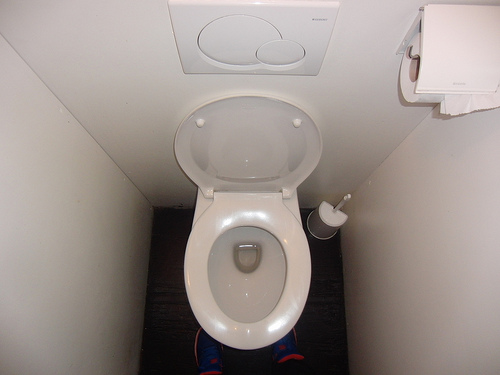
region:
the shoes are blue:
[173, 331, 311, 364]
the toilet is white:
[180, 216, 300, 311]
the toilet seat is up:
[175, 141, 322, 198]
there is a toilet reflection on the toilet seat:
[211, 140, 298, 184]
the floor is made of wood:
[153, 235, 178, 357]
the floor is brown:
[147, 253, 179, 346]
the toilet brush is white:
[307, 199, 349, 238]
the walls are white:
[408, 215, 488, 297]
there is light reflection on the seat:
[203, 210, 293, 332]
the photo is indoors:
[2, 127, 499, 372]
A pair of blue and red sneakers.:
[178, 322, 303, 372]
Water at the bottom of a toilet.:
[223, 239, 267, 279]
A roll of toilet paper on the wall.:
[390, 43, 494, 121]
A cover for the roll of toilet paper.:
[411, 7, 499, 106]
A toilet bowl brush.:
[303, 191, 355, 242]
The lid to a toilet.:
[160, 93, 334, 201]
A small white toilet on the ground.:
[166, 93, 325, 359]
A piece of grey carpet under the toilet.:
[137, 191, 356, 373]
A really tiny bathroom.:
[3, 1, 495, 371]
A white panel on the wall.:
[164, 2, 342, 87]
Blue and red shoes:
[180, 315, 311, 372]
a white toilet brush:
[310, 190, 351, 245]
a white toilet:
[156, 81, 321, 348]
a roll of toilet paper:
[390, 40, 495, 120]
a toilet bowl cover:
[165, 92, 322, 187]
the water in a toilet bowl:
[227, 235, 259, 270]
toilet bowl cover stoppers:
[191, 115, 302, 130]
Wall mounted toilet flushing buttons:
[161, 0, 336, 80]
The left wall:
[1, 40, 136, 365]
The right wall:
[333, 105, 496, 371]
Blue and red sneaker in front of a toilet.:
[188, 325, 223, 373]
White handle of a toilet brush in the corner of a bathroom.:
[333, 188, 351, 215]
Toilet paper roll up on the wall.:
[397, 31, 498, 120]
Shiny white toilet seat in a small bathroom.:
[182, 191, 311, 351]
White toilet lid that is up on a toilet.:
[173, 93, 323, 198]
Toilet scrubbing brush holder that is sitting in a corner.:
[306, 201, 346, 239]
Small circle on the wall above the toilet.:
[254, 38, 306, 67]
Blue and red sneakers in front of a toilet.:
[192, 325, 307, 373]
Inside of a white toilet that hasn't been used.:
[231, 241, 265, 272]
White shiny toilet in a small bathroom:
[173, 88, 324, 351]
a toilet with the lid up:
[148, 90, 369, 354]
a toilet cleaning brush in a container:
[312, 188, 367, 251]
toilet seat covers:
[162, 12, 345, 84]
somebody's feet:
[157, 327, 338, 372]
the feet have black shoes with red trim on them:
[180, 322, 330, 374]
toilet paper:
[390, 0, 499, 127]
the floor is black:
[158, 233, 183, 263]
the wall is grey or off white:
[395, 266, 449, 331]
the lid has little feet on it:
[194, 112, 319, 134]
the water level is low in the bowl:
[230, 241, 270, 278]